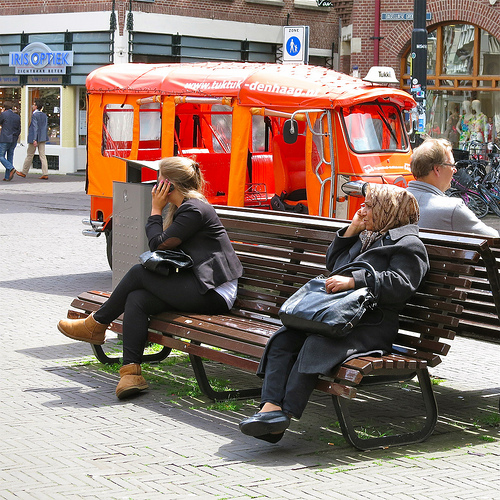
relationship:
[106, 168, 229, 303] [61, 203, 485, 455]
woman sitting on bench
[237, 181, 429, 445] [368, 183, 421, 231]
woman wearing scarf